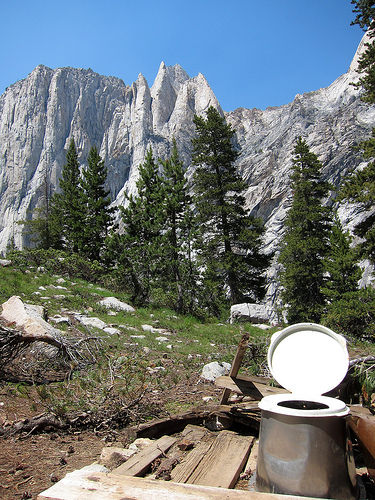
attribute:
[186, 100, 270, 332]
pine tree — tall, green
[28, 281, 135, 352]
rocks — white, large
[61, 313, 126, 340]
rocks — white, small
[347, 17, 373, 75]
mountain peek — snowy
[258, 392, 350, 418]
seat — white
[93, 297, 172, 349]
rocks — small, white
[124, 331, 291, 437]
wood — pieces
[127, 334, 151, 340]
rock — small, white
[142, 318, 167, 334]
rock — small, white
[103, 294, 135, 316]
rock — small, white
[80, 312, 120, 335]
rock — small, white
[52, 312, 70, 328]
rock — small, white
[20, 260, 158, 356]
rocks — white, small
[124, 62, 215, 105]
mountain tips — large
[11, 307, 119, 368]
rocks — small, white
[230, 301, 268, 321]
rock — white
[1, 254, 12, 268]
white rock — small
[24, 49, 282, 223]
rocks — white, small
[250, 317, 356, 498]
pot — silver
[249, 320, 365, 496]
toilet — silver, metal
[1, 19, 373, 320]
mountain range — Tall 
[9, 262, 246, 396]
rocks — white, Small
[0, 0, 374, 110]
sky — blue sky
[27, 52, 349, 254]
rocks — Small, white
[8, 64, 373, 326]
mountain — flat 